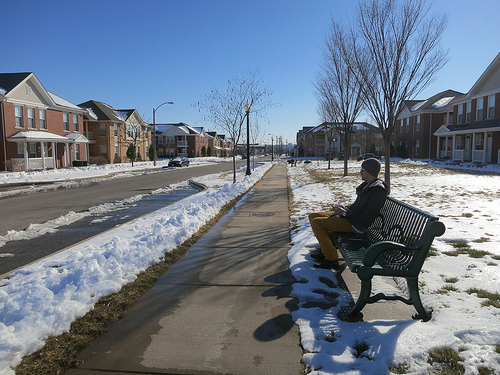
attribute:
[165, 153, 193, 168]
car — parked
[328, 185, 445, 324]
bench — black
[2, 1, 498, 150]
sky — clear, blue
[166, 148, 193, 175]
car — black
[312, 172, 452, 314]
bench — sat on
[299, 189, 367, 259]
pants — brown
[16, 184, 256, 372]
grass — green , Short 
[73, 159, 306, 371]
sidewalk — wet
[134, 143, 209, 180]
car — parked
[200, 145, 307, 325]
sidewalk — long, straight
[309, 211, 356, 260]
pants — brown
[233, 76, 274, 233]
lamp post — black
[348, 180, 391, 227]
jacket — black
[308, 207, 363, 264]
pants — brown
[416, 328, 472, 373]
grass — green , Sparse 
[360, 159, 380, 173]
hat — black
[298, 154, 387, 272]
man — sitting